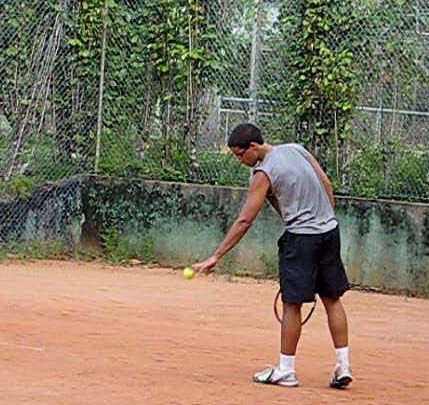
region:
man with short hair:
[176, 107, 318, 173]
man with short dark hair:
[139, 82, 345, 200]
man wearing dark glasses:
[187, 82, 318, 206]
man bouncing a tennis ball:
[146, 86, 330, 323]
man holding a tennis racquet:
[181, 106, 361, 384]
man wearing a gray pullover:
[193, 88, 348, 265]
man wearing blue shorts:
[249, 206, 376, 344]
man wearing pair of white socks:
[247, 307, 364, 375]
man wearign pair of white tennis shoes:
[234, 355, 379, 399]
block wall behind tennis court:
[0, 156, 403, 303]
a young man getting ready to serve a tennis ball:
[182, 121, 360, 386]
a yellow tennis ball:
[182, 265, 194, 279]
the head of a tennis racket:
[273, 290, 315, 323]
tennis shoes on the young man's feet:
[251, 364, 353, 389]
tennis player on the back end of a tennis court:
[2, 123, 425, 401]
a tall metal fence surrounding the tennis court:
[0, 1, 427, 203]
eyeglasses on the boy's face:
[233, 148, 248, 161]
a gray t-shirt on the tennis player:
[192, 122, 354, 389]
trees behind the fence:
[1, 1, 428, 173]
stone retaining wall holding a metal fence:
[58, 179, 186, 259]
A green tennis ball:
[177, 260, 199, 282]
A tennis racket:
[264, 261, 333, 333]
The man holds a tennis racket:
[250, 135, 369, 396]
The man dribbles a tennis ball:
[177, 108, 265, 319]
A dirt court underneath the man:
[21, 280, 247, 400]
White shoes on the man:
[251, 356, 361, 395]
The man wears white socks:
[270, 341, 365, 378]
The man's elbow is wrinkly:
[237, 218, 253, 232]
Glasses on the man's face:
[234, 147, 251, 161]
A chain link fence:
[0, 3, 428, 192]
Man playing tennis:
[169, 95, 373, 403]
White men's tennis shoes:
[252, 362, 298, 384]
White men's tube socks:
[280, 351, 294, 368]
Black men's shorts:
[274, 232, 349, 300]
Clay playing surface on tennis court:
[65, 288, 213, 359]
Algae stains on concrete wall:
[116, 180, 210, 231]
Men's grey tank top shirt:
[265, 146, 339, 232]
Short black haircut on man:
[227, 121, 266, 163]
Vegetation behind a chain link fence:
[121, 5, 207, 175]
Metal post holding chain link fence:
[91, 0, 108, 175]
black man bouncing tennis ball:
[183, 122, 353, 386]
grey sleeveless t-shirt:
[254, 146, 338, 231]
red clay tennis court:
[1, 257, 428, 402]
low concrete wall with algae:
[1, 170, 428, 298]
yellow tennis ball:
[184, 265, 195, 280]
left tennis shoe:
[252, 366, 299, 385]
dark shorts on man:
[277, 223, 351, 302]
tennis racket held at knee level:
[272, 287, 316, 320]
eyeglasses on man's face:
[233, 147, 246, 155]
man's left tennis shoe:
[327, 361, 351, 386]